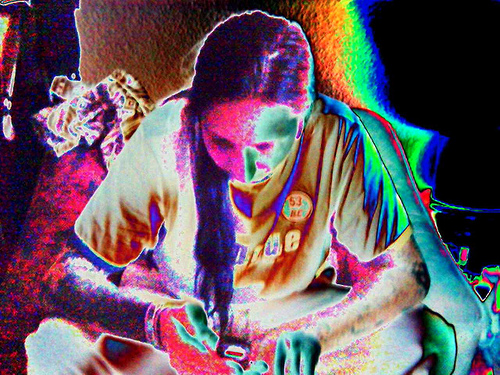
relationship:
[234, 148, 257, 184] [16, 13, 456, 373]
nose belongs to woman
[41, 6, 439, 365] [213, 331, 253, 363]
person using cell phone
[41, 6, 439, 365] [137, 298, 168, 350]
person wearing wrist watch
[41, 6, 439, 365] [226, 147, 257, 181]
person has nose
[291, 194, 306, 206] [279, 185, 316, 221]
number 53 on circle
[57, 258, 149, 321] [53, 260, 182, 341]
spots are on top of arm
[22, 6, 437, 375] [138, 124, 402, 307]
person wearing shirt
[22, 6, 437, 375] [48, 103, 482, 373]
person sitting on chair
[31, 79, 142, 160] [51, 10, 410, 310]
items are on top of chair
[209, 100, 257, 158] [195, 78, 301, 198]
spot on top of face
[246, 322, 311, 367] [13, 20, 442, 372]
hand of a person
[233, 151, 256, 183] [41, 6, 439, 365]
nose of a person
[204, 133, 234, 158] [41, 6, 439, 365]
eye of a person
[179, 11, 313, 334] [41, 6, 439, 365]
hair of a person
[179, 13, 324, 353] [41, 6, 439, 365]
hair of a person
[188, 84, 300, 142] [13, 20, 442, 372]
forehead of a person